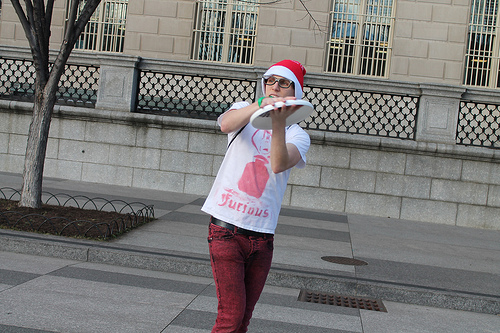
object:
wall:
[0, 46, 500, 231]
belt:
[211, 217, 273, 238]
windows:
[63, 0, 127, 53]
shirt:
[200, 102, 311, 235]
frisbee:
[250, 100, 314, 131]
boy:
[207, 59, 311, 333]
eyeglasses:
[262, 75, 294, 88]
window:
[188, 0, 259, 66]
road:
[0, 170, 500, 333]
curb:
[0, 171, 500, 333]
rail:
[297, 289, 387, 312]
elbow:
[271, 162, 288, 174]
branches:
[10, 0, 103, 88]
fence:
[0, 186, 155, 239]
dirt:
[0, 198, 154, 239]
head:
[261, 59, 306, 98]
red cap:
[262, 59, 307, 100]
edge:
[35, 97, 56, 209]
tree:
[10, 0, 102, 208]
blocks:
[0, 44, 500, 333]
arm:
[270, 120, 309, 174]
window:
[461, 0, 500, 88]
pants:
[207, 215, 274, 332]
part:
[419, 192, 433, 212]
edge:
[0, 100, 500, 164]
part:
[228, 183, 237, 193]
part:
[368, 263, 388, 277]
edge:
[0, 231, 500, 316]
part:
[235, 215, 252, 226]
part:
[215, 217, 231, 231]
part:
[268, 146, 275, 151]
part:
[273, 164, 282, 174]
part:
[346, 297, 358, 304]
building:
[0, 0, 500, 231]